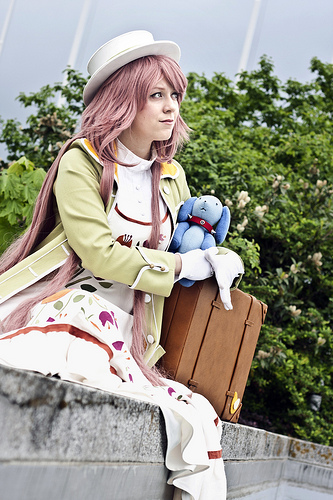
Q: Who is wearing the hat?
A: Woman holding suitcase and blue stuffed animal.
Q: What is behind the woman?
A: Green shrubs.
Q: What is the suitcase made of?
A: Leather.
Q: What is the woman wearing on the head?
A: Hat.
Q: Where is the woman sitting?
A: Raised cement platform.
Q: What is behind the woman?
A: Tree.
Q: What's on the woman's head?
A: Hat.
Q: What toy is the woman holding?
A: Dog.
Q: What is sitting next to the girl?
A: Suitcase.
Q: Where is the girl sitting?
A: Ledge.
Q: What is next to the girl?
A: Suitcase.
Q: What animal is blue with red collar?
A: Dog.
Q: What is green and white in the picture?
A: Jacket.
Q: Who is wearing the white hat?
A: The woman.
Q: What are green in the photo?
A: Bushes.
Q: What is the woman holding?
A: Stuffed animal.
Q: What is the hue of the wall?
A: Gray.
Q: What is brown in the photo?
A: Suitcase.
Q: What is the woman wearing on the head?
A: A hat.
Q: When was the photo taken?
A: Daytime.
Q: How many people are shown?
A: One.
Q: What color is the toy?
A: Blue.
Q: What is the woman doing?
A: Sitting.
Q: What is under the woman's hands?
A: Suitcase.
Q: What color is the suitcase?
A: Brown.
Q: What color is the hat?
A: White.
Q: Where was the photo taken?
A: In a park.